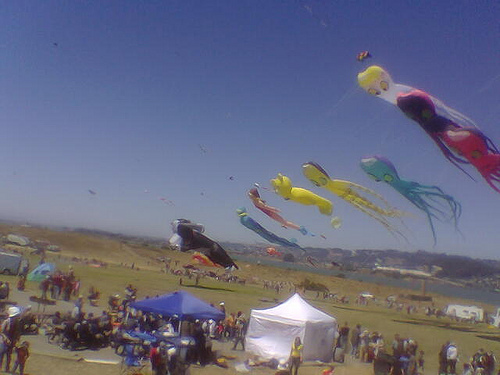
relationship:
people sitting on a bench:
[50, 310, 114, 351] [43, 322, 104, 329]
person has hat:
[0, 304, 22, 374] [0, 304, 21, 318]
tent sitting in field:
[132, 290, 226, 321] [1, 222, 496, 372]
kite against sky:
[356, 64, 500, 193] [1, 0, 498, 265]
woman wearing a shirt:
[285, 335, 305, 374] [288, 342, 302, 357]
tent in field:
[242, 292, 339, 364] [7, 250, 499, 374]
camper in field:
[446, 304, 487, 328] [1, 222, 496, 372]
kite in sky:
[268, 171, 333, 217] [1, 0, 498, 265]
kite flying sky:
[358, 67, 497, 172] [3, 2, 358, 160]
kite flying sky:
[357, 154, 467, 247] [1, 0, 498, 265]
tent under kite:
[242, 292, 338, 374] [355, 65, 499, 192]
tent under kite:
[242, 292, 338, 374] [357, 154, 467, 247]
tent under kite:
[242, 292, 338, 374] [299, 160, 415, 245]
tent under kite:
[242, 292, 338, 374] [271, 171, 333, 223]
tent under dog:
[129, 290, 226, 334] [168, 216, 239, 276]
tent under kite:
[129, 290, 226, 334] [236, 206, 306, 256]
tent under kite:
[129, 290, 226, 334] [245, 188, 308, 236]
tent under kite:
[129, 290, 226, 334] [270, 172, 333, 217]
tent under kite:
[129, 290, 226, 334] [299, 160, 419, 247]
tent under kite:
[129, 290, 226, 334] [359, 155, 466, 249]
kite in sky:
[270, 172, 333, 217] [90, 29, 197, 114]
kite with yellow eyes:
[359, 155, 466, 249] [364, 170, 399, 184]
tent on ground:
[129, 290, 226, 334] [0, 222, 500, 373]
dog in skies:
[168, 216, 239, 276] [0, 0, 500, 260]